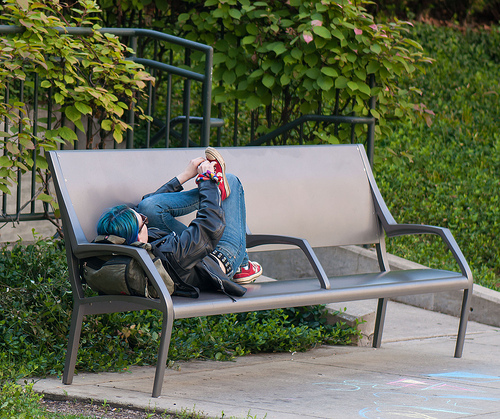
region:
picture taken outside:
[32, 19, 481, 416]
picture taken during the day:
[33, 23, 473, 416]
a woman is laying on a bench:
[25, 116, 499, 413]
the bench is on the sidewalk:
[13, 119, 484, 376]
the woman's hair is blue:
[115, 206, 133, 231]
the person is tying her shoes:
[190, 140, 242, 213]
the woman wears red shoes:
[210, 156, 235, 208]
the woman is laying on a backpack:
[83, 222, 175, 308]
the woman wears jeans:
[155, 196, 167, 213]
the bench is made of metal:
[293, 139, 404, 249]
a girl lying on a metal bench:
[83, 148, 288, 302]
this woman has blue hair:
[81, 132, 289, 322]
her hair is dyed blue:
[87, 153, 277, 333]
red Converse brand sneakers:
[206, 147, 238, 202]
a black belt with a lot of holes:
[212, 250, 237, 282]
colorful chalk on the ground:
[322, 358, 497, 415]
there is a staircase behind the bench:
[166, 107, 404, 315]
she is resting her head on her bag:
[63, 135, 311, 326]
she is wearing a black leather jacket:
[71, 133, 277, 316]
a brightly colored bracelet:
[192, 169, 224, 186]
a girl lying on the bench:
[99, 144, 266, 301]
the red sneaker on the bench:
[235, 257, 266, 287]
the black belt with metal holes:
[208, 247, 233, 281]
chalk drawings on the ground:
[303, 363, 498, 418]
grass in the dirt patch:
[0, 375, 85, 415]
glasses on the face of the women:
[136, 207, 150, 234]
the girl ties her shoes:
[171, 149, 216, 186]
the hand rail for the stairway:
[234, 107, 371, 148]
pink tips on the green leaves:
[292, 17, 410, 92]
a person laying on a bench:
[77, 149, 467, 313]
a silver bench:
[40, 144, 442, 339]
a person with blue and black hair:
[86, 186, 216, 282]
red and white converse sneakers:
[183, 142, 287, 317]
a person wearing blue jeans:
[107, 150, 285, 305]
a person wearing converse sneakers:
[91, 133, 318, 328]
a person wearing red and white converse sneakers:
[92, 139, 294, 330]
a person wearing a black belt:
[90, 150, 264, 318]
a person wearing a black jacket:
[94, 158, 259, 315]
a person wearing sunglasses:
[83, 183, 196, 285]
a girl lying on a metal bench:
[37, 138, 476, 391]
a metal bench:
[36, 140, 475, 390]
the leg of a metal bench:
[141, 316, 176, 400]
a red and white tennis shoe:
[198, 145, 233, 205]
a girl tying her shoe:
[76, 141, 265, 294]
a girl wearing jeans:
[76, 174, 249, 289]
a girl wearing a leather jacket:
[88, 173, 245, 304]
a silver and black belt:
[203, 241, 233, 288]